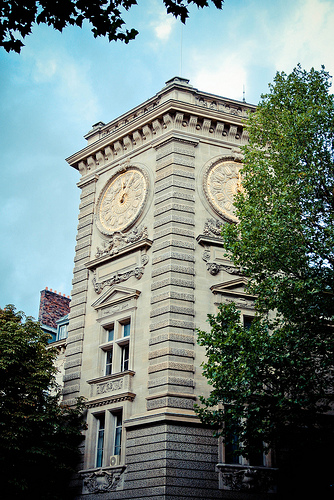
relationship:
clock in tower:
[94, 151, 256, 244] [58, 73, 303, 485]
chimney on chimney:
[40, 284, 72, 324] [35, 286, 70, 329]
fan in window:
[109, 451, 122, 464] [89, 414, 111, 463]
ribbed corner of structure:
[165, 205, 196, 416] [136, 214, 207, 464]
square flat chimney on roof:
[37, 286, 74, 334] [83, 142, 149, 163]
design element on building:
[79, 467, 125, 500] [69, 352, 188, 500]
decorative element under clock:
[94, 235, 146, 247] [96, 163, 153, 264]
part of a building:
[120, 332, 211, 500] [96, 332, 217, 500]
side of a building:
[116, 344, 187, 447] [130, 332, 204, 500]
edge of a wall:
[144, 433, 249, 500] [77, 331, 215, 500]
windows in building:
[96, 312, 133, 377] [71, 98, 238, 470]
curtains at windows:
[93, 425, 107, 464] [87, 406, 129, 461]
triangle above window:
[88, 284, 143, 306] [91, 311, 134, 371]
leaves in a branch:
[200, 306, 275, 431] [206, 320, 303, 398]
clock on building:
[94, 165, 148, 235] [59, 75, 278, 498]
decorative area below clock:
[84, 225, 152, 293] [92, 167, 145, 232]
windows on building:
[96, 312, 133, 377] [59, 75, 278, 498]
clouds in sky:
[182, 35, 252, 99] [2, 0, 333, 323]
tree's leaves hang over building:
[0, 0, 223, 54] [59, 75, 278, 498]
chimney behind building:
[35, 286, 70, 329] [34, 286, 71, 406]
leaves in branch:
[194, 299, 259, 417] [256, 364, 331, 444]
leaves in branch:
[18, 404, 58, 462] [1, 381, 35, 412]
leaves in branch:
[7, 313, 34, 359] [0, 376, 26, 411]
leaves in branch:
[220, 328, 317, 414] [304, 375, 331, 419]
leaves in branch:
[17, 386, 60, 431] [4, 410, 18, 453]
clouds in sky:
[30, 50, 101, 121] [2, 0, 333, 323]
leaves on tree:
[239, 329, 318, 412] [194, 64, 332, 462]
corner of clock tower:
[145, 76, 197, 498] [55, 76, 300, 498]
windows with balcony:
[96, 314, 132, 377] [87, 369, 137, 409]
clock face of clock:
[200, 153, 272, 224] [94, 165, 148, 235]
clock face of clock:
[96, 168, 147, 234] [201, 152, 275, 225]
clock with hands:
[94, 165, 148, 235] [119, 171, 135, 201]